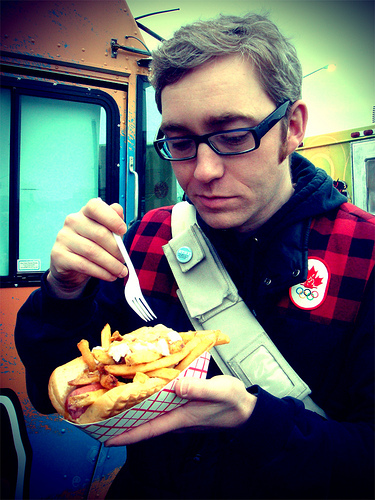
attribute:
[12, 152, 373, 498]
coat — blue, red, black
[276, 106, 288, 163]
sideburn — long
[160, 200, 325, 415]
strap — tan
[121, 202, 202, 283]
shoulder — man's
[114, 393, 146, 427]
container — paper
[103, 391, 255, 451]
hand — white, patterened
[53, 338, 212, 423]
food container — red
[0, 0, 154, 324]
bus — orange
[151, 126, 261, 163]
rim — black 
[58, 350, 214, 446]
tray — white , plastic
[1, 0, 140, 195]
structure — orange, blue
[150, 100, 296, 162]
eyeglasses — thick rimmed, black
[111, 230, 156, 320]
fork — plastic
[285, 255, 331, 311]
patch — white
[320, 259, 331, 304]
border — red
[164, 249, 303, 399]
tan strap — thick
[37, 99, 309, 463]
container — patterned, red, white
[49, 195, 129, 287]
hand — white, plastic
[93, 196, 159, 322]
fork — disposable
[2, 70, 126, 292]
window — two pane, black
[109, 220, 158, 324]
fork — plastic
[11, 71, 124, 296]
frame — thick